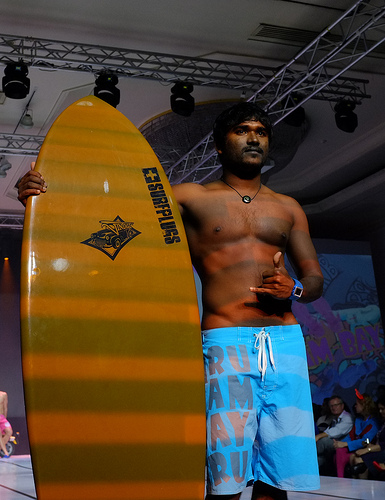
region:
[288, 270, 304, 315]
A BLUE WATCH ON A WRIST.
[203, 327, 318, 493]
BLUE SHORTS WORN BY A MAN.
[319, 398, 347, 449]
A MAN IN THE AUDIENCE.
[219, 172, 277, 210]
A PIECE OF NECKLACE WORN.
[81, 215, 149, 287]
A LOGO ON THE SURFBOARD.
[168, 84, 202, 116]
BLACK LIGHTS ON THE CEILING.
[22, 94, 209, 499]
A YELLOW SURFBOARD IS HELD.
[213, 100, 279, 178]
THE PICTURE IS OF A MAN.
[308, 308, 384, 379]
GRAFITTI ON THE WALL.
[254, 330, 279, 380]
WHITE STRINGS TIE THE SHORTS.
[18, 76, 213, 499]
Large orange wooden surfboard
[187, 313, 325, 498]
Pair of blue shorts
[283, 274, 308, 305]
Blue plastic smart watch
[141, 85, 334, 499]
Person wearing a smart watch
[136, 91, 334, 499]
person wearing blue shorts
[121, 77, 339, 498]
Person wearing shorts and necklace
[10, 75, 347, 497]
Person holding a surfboard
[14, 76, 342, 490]
Person wearing shorts and holding a surfboard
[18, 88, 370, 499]
Person wearing a smart watch and holding a surfboard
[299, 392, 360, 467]
Person wearing a white shirt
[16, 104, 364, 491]
man wearing blue shorts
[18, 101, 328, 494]
man holding a yellow surfboard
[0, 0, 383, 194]
track lights hanging from ceiling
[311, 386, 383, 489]
crowd of people looking on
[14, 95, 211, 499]
yellow surfboard with black writing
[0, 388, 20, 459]
person sitting on bike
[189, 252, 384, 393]
wall with graffiti written on it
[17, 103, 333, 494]
man wearing black necklace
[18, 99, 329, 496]
man wearing blue watch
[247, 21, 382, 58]
metal vent attached to ceiling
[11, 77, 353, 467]
person standing with surfboard.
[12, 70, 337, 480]
person modeling with surfboard.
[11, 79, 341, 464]
person holding a surfboard.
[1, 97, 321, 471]
man standing with surfboard.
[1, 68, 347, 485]
man modeling with surfboard.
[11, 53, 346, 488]
man holding a large surfboard.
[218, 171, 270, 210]
person wearing a necklace.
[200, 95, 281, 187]
person with dark colored hair.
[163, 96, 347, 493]
man wearing blue shorts.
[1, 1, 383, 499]
male surfer on stage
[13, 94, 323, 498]
surfer holding yellow surfboard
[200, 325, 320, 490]
blue striped swim trunks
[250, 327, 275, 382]
white drawstring tie on trunks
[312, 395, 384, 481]
audience watching surfer on stage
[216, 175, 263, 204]
simple black and silver necklace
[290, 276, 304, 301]
blue and white wristwatch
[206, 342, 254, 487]
gray letters on trunks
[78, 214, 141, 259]
black design on surfboard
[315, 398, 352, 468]
man in white shirt